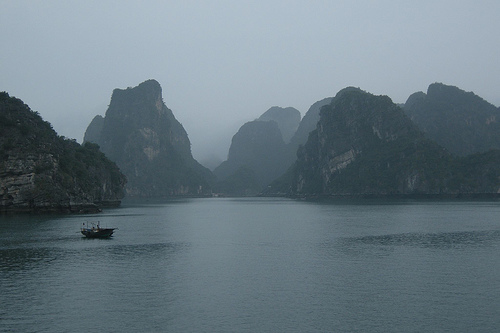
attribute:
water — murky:
[146, 214, 428, 331]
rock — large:
[265, 77, 485, 229]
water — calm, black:
[142, 199, 340, 240]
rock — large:
[59, 62, 427, 208]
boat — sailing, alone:
[76, 215, 123, 243]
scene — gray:
[32, 34, 460, 311]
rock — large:
[201, 113, 295, 203]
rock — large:
[252, 82, 492, 200]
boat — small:
[82, 218, 112, 244]